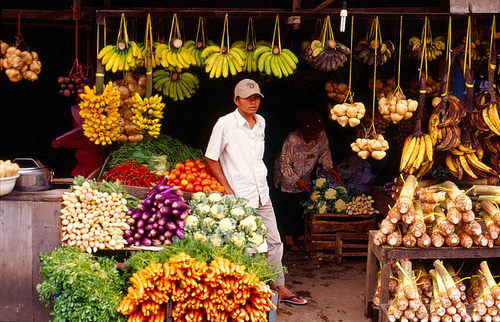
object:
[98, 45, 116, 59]
bananas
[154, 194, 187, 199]
eggplant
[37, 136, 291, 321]
produce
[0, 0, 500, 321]
market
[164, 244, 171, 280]
carrots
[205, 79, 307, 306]
man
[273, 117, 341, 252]
woman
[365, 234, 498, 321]
stand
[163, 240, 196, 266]
tops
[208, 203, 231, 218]
cabbage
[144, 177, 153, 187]
peppers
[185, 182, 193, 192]
tomatoes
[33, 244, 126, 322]
lettuce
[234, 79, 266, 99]
hat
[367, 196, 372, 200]
leeks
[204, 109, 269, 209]
shirt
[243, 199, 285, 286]
pants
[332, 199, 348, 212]
cauliflower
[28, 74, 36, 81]
garlic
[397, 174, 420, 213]
turnips